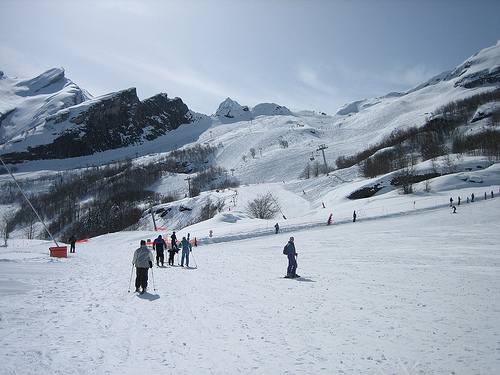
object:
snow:
[0, 40, 499, 373]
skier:
[131, 239, 156, 294]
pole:
[127, 261, 137, 292]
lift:
[314, 142, 330, 175]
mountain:
[0, 39, 499, 252]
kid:
[167, 246, 180, 267]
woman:
[177, 238, 193, 267]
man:
[150, 234, 168, 265]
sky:
[0, 0, 499, 116]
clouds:
[126, 55, 227, 97]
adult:
[281, 235, 300, 278]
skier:
[352, 210, 358, 223]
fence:
[74, 237, 89, 244]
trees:
[7, 142, 220, 242]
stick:
[319, 145, 329, 172]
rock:
[346, 176, 394, 201]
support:
[0, 158, 70, 258]